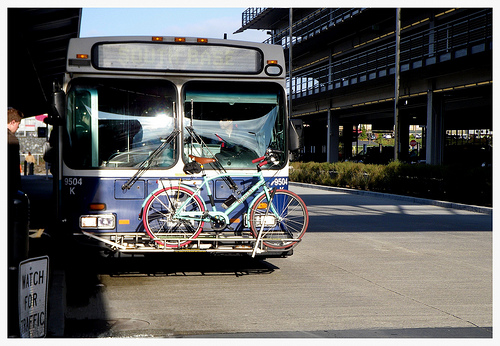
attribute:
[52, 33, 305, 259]
bus — here, parked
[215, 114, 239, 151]
driver — driving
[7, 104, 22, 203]
man — waiting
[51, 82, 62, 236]
door — open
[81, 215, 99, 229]
light — on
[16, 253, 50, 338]
sign — informative, black, white, metal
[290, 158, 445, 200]
shrub — green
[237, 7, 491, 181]
building — metal, concrete, blue, shadowy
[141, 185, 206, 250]
wheel — red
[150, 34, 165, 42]
top light — orange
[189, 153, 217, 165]
seat — brown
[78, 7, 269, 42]
sky — blue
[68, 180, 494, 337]
street — grey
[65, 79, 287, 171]
windshield — shiny